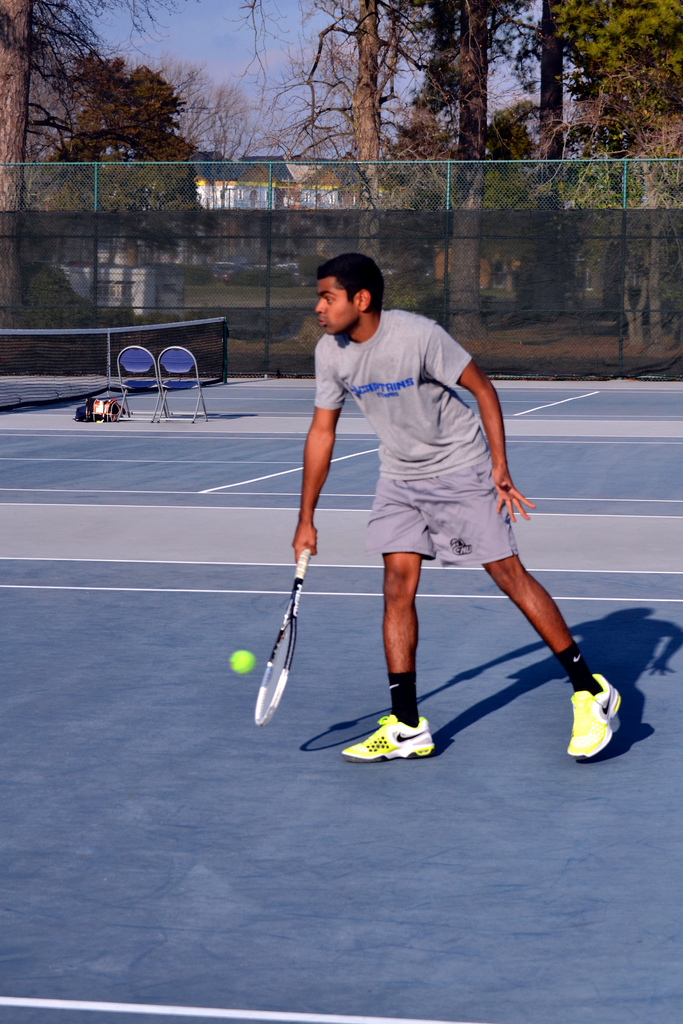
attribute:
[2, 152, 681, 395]
fence — tall, chain link, green, painted 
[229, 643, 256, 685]
tennis ball — green , bright 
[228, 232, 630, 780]
man — young 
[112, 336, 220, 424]
folding chairs — blue 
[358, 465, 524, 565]
athletic shorts — grey 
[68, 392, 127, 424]
tennis bag — black , white  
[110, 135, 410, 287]
building — large  , colorful   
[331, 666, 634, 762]
tennis shoes — Yellow , white 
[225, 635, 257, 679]
tennis ball — green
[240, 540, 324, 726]
tennis racket — Black , white 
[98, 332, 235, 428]
folding chairs — metal  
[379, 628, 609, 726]
socks — black   , nike 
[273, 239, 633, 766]
tennis player — male 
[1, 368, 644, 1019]
court — half , green , white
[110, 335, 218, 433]
chair — fold up, blue 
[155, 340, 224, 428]
chair — blue , fold up